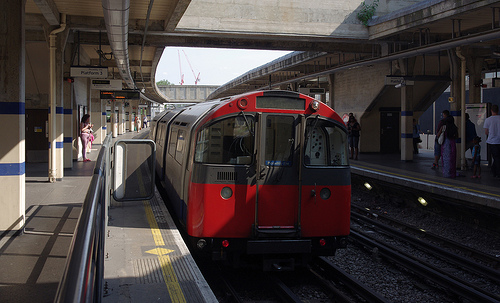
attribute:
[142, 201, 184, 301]
paint — yellow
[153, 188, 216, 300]
paint — white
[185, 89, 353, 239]
paint — red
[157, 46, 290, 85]
sky — open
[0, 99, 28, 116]
paint — blue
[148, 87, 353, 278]
train — red, black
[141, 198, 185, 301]
line — yellow